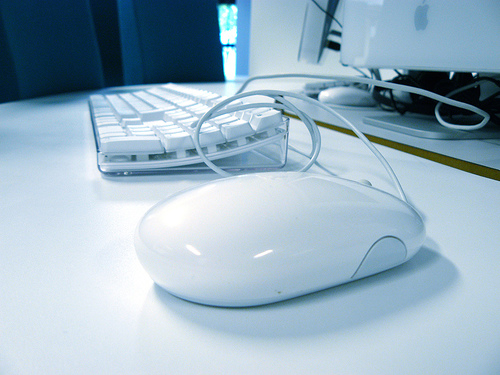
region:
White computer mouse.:
[136, 165, 419, 303]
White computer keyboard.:
[67, 87, 276, 175]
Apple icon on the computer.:
[400, 0, 443, 40]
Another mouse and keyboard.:
[311, 63, 381, 116]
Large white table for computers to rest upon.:
[29, 85, 499, 373]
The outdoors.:
[206, 1, 253, 79]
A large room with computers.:
[1, 0, 498, 333]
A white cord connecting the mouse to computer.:
[235, 62, 473, 197]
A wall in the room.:
[19, 0, 184, 91]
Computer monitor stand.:
[377, 100, 474, 151]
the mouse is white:
[137, 181, 297, 341]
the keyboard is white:
[53, 68, 280, 205]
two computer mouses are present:
[118, 40, 456, 371]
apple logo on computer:
[398, 0, 444, 55]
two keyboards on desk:
[63, 18, 371, 185]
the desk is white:
[8, 269, 150, 374]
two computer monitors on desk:
[199, 1, 463, 100]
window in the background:
[196, 20, 254, 65]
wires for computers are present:
[211, 36, 496, 178]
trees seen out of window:
[206, 7, 267, 69]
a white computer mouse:
[144, 173, 431, 296]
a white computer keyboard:
[89, 88, 281, 165]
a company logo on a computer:
[407, 1, 439, 39]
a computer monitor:
[301, 3, 339, 72]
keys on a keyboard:
[114, 96, 171, 137]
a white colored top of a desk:
[19, 138, 95, 325]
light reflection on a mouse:
[170, 225, 292, 281]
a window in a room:
[204, 11, 240, 73]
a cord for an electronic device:
[224, 86, 369, 168]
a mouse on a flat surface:
[106, 155, 431, 323]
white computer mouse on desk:
[129, 161, 433, 317]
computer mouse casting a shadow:
[120, 156, 459, 328]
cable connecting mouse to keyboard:
[207, 74, 464, 200]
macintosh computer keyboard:
[67, 68, 304, 176]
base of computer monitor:
[311, 48, 494, 149]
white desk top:
[10, 41, 492, 353]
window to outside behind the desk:
[204, 1, 246, 83]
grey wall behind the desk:
[5, 2, 242, 102]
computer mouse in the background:
[314, 81, 389, 119]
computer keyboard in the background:
[301, 73, 369, 92]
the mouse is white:
[163, 170, 391, 328]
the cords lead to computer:
[210, 91, 375, 177]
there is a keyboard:
[90, 90, 231, 145]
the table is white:
[7, 162, 162, 368]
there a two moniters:
[250, 10, 496, 72]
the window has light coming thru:
[225, 5, 262, 70]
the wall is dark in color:
[0, 15, 200, 80]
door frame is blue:
[235, 0, 245, 76]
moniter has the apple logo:
[405, 0, 445, 46]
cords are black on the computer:
[328, 26, 343, 62]